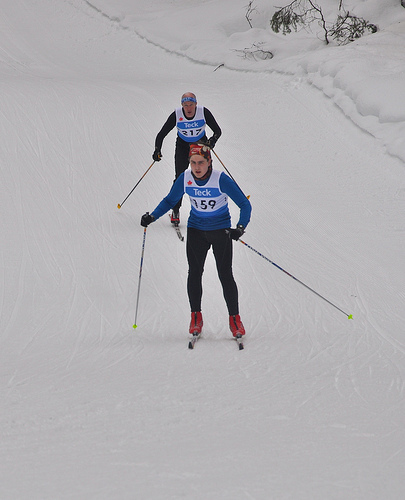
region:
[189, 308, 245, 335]
pair of red ski boots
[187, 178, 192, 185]
red star on right shoulder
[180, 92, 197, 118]
blue headband on head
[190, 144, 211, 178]
red hat on head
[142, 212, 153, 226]
black glove on right hand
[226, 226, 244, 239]
black glove on left hand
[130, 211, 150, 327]
right ski pole with yellow tip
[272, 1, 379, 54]
dead pine tree in snow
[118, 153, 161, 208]
right ski pole with orange tip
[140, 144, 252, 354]
skier in blue and white shirt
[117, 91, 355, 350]
two competitors skiing on a snowy slope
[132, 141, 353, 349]
competitor 159 holding two ski poles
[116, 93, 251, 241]
competitor 217 holding ski poles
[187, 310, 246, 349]
red snow boots on skis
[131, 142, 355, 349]
female competitor 159 skiing down a slope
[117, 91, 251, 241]
competitor 217 skiing down a slope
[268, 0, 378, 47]
tree branches in the snow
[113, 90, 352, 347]
winter sport skiing competition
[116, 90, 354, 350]
male and female ski competitors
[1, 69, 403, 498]
man and woman skiing on the snow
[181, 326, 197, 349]
tip of a skater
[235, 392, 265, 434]
part of a skater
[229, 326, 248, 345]
part of some shoes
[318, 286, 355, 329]
part of a hooker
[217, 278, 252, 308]
part of a trouser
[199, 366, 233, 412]
part of a snow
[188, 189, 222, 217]
blue and white race bib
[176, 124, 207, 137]
blue and white race bib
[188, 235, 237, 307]
blue pants worn by skier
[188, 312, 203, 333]
red ski boot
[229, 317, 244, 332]
red ski boot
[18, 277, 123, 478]
white snow on mountain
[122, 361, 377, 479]
white snow on mountain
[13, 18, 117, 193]
white snow on mountain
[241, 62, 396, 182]
white snow on mountain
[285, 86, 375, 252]
white snow on mountain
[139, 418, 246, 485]
The snow is white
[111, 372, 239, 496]
The snow is white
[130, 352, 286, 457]
The snow is white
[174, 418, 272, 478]
The snow is white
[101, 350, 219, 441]
The snow is white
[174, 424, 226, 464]
The snow is white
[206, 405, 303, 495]
The snow is white